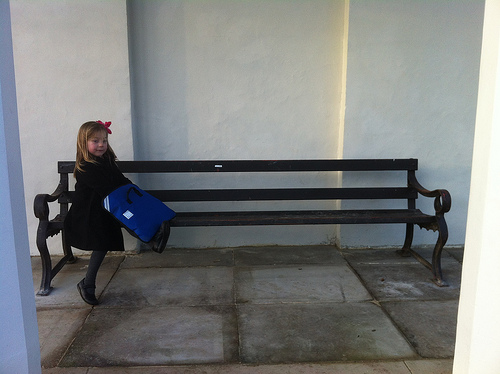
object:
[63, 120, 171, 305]
girl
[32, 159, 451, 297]
bench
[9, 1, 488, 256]
wall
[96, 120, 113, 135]
ribbon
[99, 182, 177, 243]
bag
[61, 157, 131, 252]
jacket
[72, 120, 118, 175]
hair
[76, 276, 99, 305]
shoe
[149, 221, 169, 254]
shoe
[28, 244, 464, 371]
floor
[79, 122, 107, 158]
head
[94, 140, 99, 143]
eye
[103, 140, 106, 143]
eye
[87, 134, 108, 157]
face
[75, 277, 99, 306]
foot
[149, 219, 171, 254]
foot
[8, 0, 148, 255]
side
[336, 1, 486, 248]
side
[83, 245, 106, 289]
tights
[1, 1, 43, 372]
wall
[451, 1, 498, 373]
wall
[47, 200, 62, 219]
opening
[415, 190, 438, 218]
opening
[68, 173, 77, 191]
opening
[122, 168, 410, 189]
opening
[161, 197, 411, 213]
opening